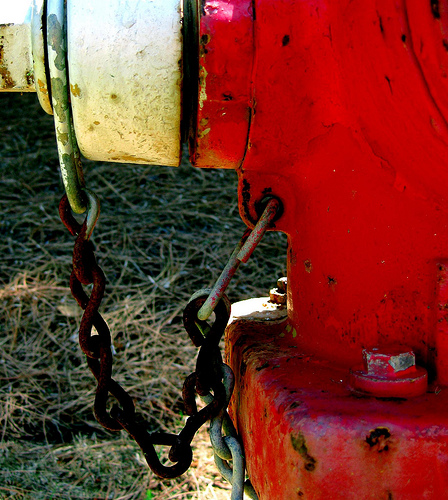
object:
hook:
[197, 201, 279, 321]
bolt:
[268, 275, 288, 305]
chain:
[58, 184, 283, 499]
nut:
[347, 343, 427, 399]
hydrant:
[1, 1, 445, 497]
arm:
[2, 0, 188, 167]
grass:
[0, 105, 287, 499]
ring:
[44, 0, 88, 214]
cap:
[348, 344, 429, 398]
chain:
[56, 190, 290, 499]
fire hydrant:
[1, 0, 446, 499]